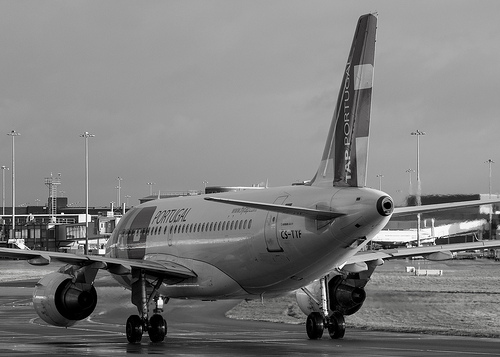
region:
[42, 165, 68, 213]
long tower in the background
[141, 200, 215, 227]
black words on side of plane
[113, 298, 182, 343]
black wheels on plane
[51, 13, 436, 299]
large plane on the tarmac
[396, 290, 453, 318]
grass at side of track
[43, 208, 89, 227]
window in square building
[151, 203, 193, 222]
Portugal written on plane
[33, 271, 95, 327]
jet engine on plane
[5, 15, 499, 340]
white and gray plane on tarmac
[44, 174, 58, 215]
air traffic control tower in background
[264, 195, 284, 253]
rear door on plane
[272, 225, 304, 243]
black letters on back of plane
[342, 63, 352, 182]
white letters on tail of plane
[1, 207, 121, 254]
airport terminal in background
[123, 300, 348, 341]
black wheels on the plane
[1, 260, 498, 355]
airport tarmac with white lines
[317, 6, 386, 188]
tail of the plane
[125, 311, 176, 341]
wheels of the plane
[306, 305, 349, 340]
wheels are black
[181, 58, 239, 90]
the sky is grey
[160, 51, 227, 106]
a grey sky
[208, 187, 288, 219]
wing on the plane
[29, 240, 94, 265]
the planes wing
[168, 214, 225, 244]
windows on the plane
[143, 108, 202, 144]
a cloud in the sky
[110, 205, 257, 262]
windows on side of plane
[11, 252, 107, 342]
engine on side of plane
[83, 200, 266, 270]
side of the plane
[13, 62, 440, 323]
black and white plane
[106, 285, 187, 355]
wheels on bottom of plane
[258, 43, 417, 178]
tail of the plane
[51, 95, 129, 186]
pole in the distance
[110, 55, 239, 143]
sky above the land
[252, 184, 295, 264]
door on back of plane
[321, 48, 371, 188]
writing on the tail of plane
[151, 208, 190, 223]
PORTUGAL on a plane side.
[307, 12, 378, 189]
Tail end of a plane.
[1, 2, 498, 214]
A grey sky.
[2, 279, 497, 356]
A paved runway.